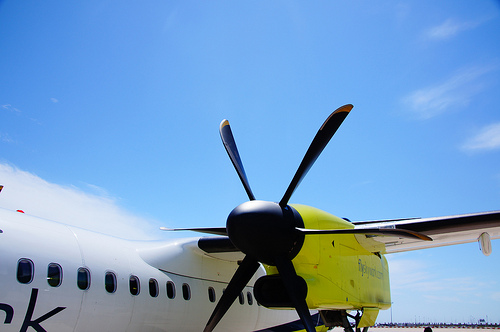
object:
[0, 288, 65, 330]
letter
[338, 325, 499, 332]
land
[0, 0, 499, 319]
sky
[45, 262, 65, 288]
window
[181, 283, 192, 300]
window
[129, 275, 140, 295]
window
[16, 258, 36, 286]
window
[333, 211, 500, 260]
wing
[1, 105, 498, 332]
plane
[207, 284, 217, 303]
window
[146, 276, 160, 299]
window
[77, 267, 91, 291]
window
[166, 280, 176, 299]
window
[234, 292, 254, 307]
windows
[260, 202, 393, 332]
part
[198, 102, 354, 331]
propellor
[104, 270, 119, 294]
window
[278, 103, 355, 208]
blade